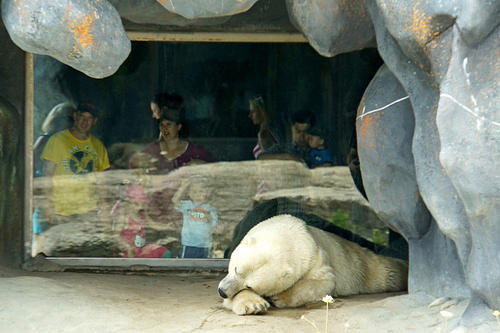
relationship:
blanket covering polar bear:
[240, 176, 360, 243] [234, 215, 374, 323]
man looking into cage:
[39, 106, 110, 233] [0, 0, 499, 328]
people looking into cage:
[237, 92, 361, 193] [0, 0, 499, 328]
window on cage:
[33, 54, 389, 257] [0, 0, 499, 328]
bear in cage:
[217, 213, 409, 316] [0, 0, 499, 328]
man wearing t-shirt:
[41, 100, 110, 252] [42, 127, 110, 217]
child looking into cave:
[110, 182, 173, 256] [224, 191, 408, 259]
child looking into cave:
[170, 173, 223, 255] [224, 191, 408, 259]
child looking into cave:
[301, 127, 331, 164] [224, 191, 408, 259]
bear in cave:
[217, 213, 409, 316] [224, 191, 408, 259]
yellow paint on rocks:
[403, 12, 458, 60] [358, 2, 498, 309]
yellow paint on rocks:
[60, 9, 105, 46] [3, 1, 134, 79]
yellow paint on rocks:
[361, 97, 384, 148] [163, 0, 370, 62]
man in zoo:
[39, 106, 110, 233] [0, 0, 498, 332]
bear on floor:
[185, 199, 430, 320] [0, 271, 406, 330]